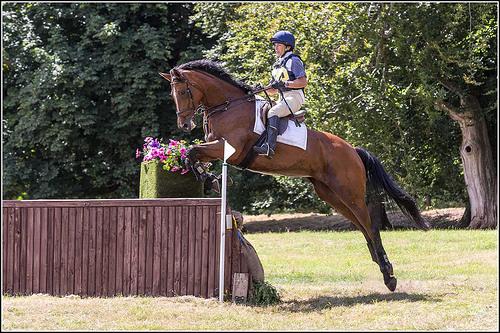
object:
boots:
[251, 114, 283, 158]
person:
[250, 29, 307, 158]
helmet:
[269, 29, 296, 49]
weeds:
[251, 277, 288, 312]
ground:
[4, 188, 496, 325]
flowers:
[134, 131, 213, 180]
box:
[128, 155, 208, 197]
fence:
[3, 198, 265, 303]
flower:
[167, 162, 181, 173]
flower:
[177, 161, 189, 176]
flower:
[132, 145, 142, 156]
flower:
[143, 132, 155, 144]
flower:
[202, 159, 214, 169]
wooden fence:
[0, 195, 265, 303]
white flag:
[224, 141, 234, 160]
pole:
[218, 164, 230, 304]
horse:
[158, 60, 428, 291]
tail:
[358, 145, 433, 234]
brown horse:
[159, 61, 428, 291]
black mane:
[172, 60, 251, 92]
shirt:
[266, 56, 309, 102]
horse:
[148, 46, 440, 294]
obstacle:
[3, 187, 275, 307]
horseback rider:
[251, 28, 306, 160]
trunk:
[426, 80, 498, 244]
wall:
[4, 119, 305, 308]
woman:
[246, 29, 309, 158]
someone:
[217, 28, 352, 202]